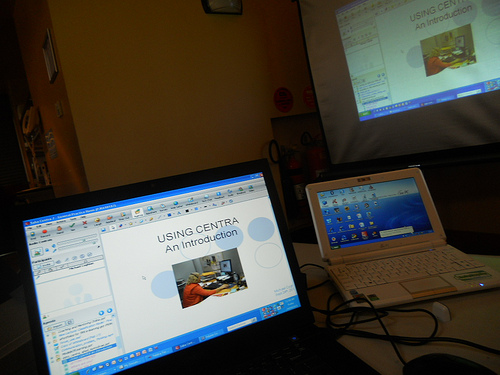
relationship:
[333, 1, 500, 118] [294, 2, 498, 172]
presentation on screen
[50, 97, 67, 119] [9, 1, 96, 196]
switch on wall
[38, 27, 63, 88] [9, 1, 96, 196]
picture on wall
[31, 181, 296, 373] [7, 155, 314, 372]
website on monitor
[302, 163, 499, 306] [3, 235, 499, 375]
laptop on table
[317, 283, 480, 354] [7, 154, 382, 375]
cables for laptop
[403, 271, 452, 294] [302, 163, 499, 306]
mouse pad on laptop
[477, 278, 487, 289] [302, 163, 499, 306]
power light on front of laptop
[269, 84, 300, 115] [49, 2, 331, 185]
sticker on wall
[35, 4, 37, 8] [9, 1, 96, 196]
paint on wall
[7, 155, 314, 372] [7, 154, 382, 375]
monitor of laptop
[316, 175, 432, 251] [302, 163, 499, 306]
screen of laptop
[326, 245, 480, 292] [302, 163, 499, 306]
keyboard of laptop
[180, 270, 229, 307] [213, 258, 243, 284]
woman using computer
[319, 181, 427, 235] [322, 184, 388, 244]
desktop background with icons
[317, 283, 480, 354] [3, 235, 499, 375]
cables on table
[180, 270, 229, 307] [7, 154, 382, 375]
woman on laptop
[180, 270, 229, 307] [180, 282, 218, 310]
woman wearing shirt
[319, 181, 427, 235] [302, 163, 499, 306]
desktop background on laptop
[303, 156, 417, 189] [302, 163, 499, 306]
edge of laptop